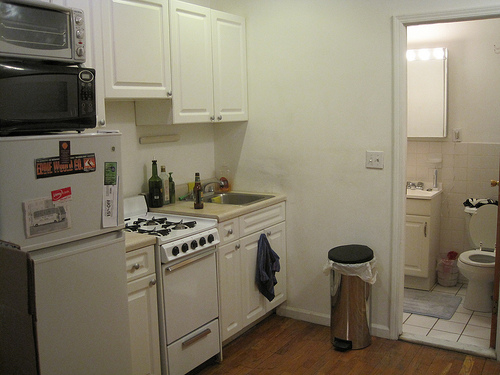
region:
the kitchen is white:
[213, 47, 323, 128]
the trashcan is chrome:
[323, 222, 404, 372]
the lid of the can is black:
[320, 237, 381, 273]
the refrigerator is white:
[11, 127, 152, 373]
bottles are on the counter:
[147, 150, 182, 210]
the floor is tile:
[423, 307, 485, 350]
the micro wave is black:
[0, 63, 109, 135]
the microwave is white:
[3, 7, 105, 69]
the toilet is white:
[448, 194, 498, 316]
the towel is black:
[253, 225, 284, 307]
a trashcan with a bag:
[285, 194, 425, 363]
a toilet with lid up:
[398, 172, 498, 324]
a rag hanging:
[181, 193, 331, 340]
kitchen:
[4, 67, 430, 360]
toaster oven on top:
[1, 3, 131, 76]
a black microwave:
[0, 77, 180, 139]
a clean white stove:
[77, 46, 384, 351]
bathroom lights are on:
[400, 31, 493, 171]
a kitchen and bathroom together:
[27, 0, 470, 291]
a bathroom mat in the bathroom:
[364, 240, 466, 334]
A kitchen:
[108, 75, 334, 374]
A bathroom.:
[411, 29, 498, 317]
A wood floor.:
[249, 340, 411, 372]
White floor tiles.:
[416, 317, 484, 342]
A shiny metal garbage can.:
[331, 231, 371, 373]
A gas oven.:
[151, 205, 213, 362]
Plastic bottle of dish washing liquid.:
[200, 153, 243, 198]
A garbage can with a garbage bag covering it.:
[433, 247, 458, 283]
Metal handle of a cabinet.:
[147, 280, 153, 291]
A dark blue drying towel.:
[251, 232, 286, 298]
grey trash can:
[315, 236, 414, 371]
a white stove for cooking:
[128, 199, 248, 350]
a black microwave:
[0, 56, 110, 132]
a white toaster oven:
[0, 8, 119, 74]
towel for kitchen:
[249, 228, 289, 350]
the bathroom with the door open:
[412, 75, 487, 337]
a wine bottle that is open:
[143, 158, 181, 200]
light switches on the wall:
[351, 143, 391, 176]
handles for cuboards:
[128, 260, 168, 295]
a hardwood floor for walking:
[266, 338, 328, 368]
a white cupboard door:
[212, 9, 252, 121]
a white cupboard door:
[172, 1, 213, 126]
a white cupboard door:
[102, 0, 170, 100]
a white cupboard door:
[243, 221, 294, 314]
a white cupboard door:
[215, 238, 255, 343]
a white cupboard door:
[122, 273, 177, 373]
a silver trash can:
[316, 237, 376, 354]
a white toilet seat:
[447, 185, 499, 313]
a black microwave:
[1, 61, 93, 128]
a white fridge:
[0, 127, 127, 369]